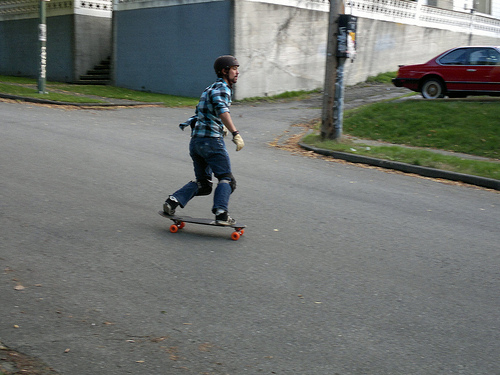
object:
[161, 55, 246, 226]
man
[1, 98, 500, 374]
road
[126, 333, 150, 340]
crack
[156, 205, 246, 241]
skateboard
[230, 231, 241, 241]
wheel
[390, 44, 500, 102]
car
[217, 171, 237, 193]
kneepad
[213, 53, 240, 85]
helmet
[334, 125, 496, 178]
sidewalk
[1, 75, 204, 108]
grass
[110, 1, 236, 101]
wall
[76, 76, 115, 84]
stairs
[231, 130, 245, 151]
glove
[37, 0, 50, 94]
pole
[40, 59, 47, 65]
writing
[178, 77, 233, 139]
shirt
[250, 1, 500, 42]
rail